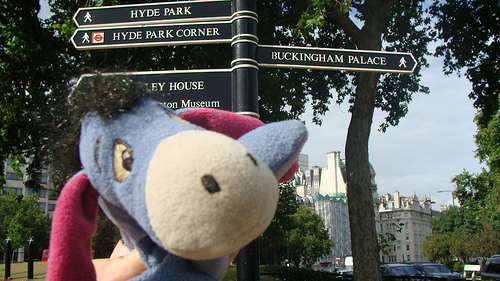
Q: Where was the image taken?
A: It was taken at the park.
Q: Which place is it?
A: It is a park.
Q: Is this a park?
A: Yes, it is a park.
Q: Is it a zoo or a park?
A: It is a park.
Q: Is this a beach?
A: No, it is a park.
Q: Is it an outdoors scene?
A: Yes, it is outdoors.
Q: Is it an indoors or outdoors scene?
A: It is outdoors.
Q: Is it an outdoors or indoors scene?
A: It is outdoors.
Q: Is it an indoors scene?
A: No, it is outdoors.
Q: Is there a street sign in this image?
A: Yes, there is a street sign.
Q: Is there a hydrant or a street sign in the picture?
A: Yes, there is a street sign.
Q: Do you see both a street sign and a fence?
A: No, there is a street sign but no fences.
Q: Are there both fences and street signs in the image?
A: No, there is a street sign but no fences.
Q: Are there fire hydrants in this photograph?
A: No, there are no fire hydrants.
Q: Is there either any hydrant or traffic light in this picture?
A: No, there are no fire hydrants or traffic lights.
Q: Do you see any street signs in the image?
A: Yes, there is a street sign.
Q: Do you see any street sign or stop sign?
A: Yes, there is a street sign.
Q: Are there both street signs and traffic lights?
A: No, there is a street sign but no traffic lights.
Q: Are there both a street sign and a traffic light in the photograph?
A: No, there is a street sign but no traffic lights.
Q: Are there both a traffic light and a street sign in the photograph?
A: No, there is a street sign but no traffic lights.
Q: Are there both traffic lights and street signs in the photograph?
A: No, there is a street sign but no traffic lights.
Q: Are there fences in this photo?
A: No, there are no fences.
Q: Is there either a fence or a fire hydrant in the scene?
A: No, there are no fences or fire hydrants.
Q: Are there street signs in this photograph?
A: Yes, there is a street sign.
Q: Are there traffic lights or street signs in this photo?
A: Yes, there is a street sign.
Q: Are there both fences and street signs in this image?
A: No, there is a street sign but no fences.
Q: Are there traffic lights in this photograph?
A: No, there are no traffic lights.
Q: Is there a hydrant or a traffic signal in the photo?
A: No, there are no traffic lights or fire hydrants.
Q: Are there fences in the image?
A: No, there are no fences.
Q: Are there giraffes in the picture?
A: No, there are no giraffes.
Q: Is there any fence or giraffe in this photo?
A: No, there are no giraffes or fences.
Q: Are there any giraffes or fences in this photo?
A: No, there are no giraffes or fences.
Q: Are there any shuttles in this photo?
A: No, there are no shuttles.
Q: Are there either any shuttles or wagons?
A: No, there are no shuttles or wagons.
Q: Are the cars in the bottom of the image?
A: Yes, the cars are in the bottom of the image.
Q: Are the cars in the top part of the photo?
A: No, the cars are in the bottom of the image.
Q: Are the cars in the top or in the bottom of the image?
A: The cars are in the bottom of the image.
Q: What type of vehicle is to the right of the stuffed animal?
A: The vehicles are cars.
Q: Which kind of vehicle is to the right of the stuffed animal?
A: The vehicles are cars.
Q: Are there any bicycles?
A: No, there are no bicycles.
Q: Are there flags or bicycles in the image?
A: No, there are no bicycles or flags.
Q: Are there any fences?
A: No, there are no fences.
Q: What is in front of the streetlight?
A: The trees are in front of the streetlight.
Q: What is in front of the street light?
A: The trees are in front of the streetlight.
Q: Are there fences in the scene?
A: No, there are no fences.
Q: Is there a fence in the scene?
A: No, there are no fences.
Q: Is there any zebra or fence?
A: No, there are no fences or zebras.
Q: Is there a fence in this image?
A: No, there are no fences.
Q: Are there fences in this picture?
A: No, there are no fences.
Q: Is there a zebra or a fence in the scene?
A: No, there are no fences or zebras.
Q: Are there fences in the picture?
A: No, there are no fences.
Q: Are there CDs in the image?
A: No, there are no cds.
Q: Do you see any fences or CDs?
A: No, there are no CDs or fences.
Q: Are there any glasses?
A: No, there are no glasses.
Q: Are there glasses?
A: No, there are no glasses.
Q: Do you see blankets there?
A: No, there are no blankets.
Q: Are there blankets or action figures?
A: No, there are no blankets or action figures.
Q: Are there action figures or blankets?
A: No, there are no blankets or action figures.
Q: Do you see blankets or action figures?
A: No, there are no blankets or action figures.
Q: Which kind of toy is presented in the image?
A: The toy is a stuffed animal.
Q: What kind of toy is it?
A: The toy is a stuffed animal.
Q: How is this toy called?
A: This is a stuffed animal.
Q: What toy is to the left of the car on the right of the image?
A: The toy is a stuffed animal.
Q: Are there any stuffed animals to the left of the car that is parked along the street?
A: Yes, there is a stuffed animal to the left of the car.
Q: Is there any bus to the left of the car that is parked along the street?
A: No, there is a stuffed animal to the left of the car.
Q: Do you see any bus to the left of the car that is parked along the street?
A: No, there is a stuffed animal to the left of the car.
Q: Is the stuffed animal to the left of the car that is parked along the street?
A: Yes, the stuffed animal is to the left of the car.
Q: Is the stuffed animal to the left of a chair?
A: No, the stuffed animal is to the left of the car.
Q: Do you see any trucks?
A: No, there are no trucks.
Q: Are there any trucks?
A: No, there are no trucks.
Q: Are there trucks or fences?
A: No, there are no trucks or fences.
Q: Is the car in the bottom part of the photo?
A: Yes, the car is in the bottom of the image.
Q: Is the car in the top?
A: No, the car is in the bottom of the image.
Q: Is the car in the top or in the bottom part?
A: The car is in the bottom of the image.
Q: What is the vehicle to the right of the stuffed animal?
A: The vehicle is a car.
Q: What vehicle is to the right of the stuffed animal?
A: The vehicle is a car.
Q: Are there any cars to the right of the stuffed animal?
A: Yes, there is a car to the right of the stuffed animal.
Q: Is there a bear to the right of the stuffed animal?
A: No, there is a car to the right of the stuffed animal.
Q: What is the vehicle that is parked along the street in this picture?
A: The vehicle is a car.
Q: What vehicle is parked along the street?
A: The vehicle is a car.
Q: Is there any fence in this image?
A: No, there are no fences.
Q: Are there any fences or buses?
A: No, there are no fences or buses.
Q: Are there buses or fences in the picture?
A: No, there are no fences or buses.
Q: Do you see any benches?
A: No, there are no benches.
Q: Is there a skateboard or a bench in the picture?
A: No, there are no benches or skateboards.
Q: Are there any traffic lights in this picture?
A: No, there are no traffic lights.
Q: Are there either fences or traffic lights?
A: No, there are no traffic lights or fences.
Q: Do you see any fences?
A: No, there are no fences.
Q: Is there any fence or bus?
A: No, there are no fences or buses.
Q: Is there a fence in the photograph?
A: No, there are no fences.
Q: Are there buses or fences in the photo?
A: No, there are no fences or buses.